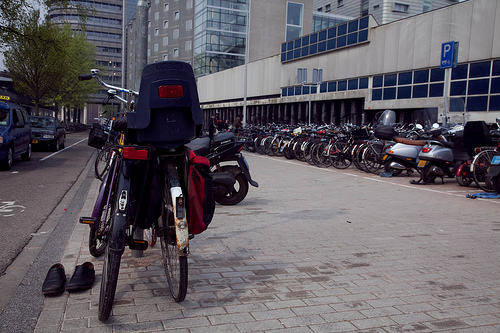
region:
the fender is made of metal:
[111, 155, 136, 245]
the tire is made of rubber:
[102, 245, 122, 321]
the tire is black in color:
[100, 246, 119, 321]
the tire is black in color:
[172, 248, 190, 300]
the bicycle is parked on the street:
[77, 78, 134, 320]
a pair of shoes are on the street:
[46, 259, 99, 297]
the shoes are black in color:
[44, 260, 94, 292]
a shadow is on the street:
[120, 244, 291, 331]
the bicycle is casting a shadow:
[109, 80, 306, 325]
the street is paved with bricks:
[56, 116, 479, 331]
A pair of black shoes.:
[40, 258, 99, 296]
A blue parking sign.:
[438, 37, 460, 72]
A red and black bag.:
[177, 142, 217, 234]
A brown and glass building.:
[193, 0, 315, 80]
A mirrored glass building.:
[122, 0, 193, 93]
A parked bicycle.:
[470, 121, 499, 191]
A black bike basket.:
[86, 120, 108, 150]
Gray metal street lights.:
[296, 67, 324, 127]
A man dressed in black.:
[206, 110, 220, 142]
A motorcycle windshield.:
[372, 110, 399, 131]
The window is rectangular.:
[369, 70, 385, 88]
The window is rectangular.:
[382, 68, 399, 87]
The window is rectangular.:
[395, 66, 414, 86]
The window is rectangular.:
[411, 61, 431, 84]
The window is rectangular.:
[428, 63, 448, 84]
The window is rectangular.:
[447, 59, 469, 81]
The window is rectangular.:
[466, 58, 493, 80]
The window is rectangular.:
[463, 74, 491, 96]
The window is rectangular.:
[463, 94, 492, 112]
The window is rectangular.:
[394, 83, 414, 100]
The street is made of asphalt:
[28, 163, 65, 200]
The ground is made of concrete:
[294, 206, 446, 305]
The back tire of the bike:
[89, 218, 138, 323]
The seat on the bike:
[121, 53, 210, 152]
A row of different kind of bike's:
[243, 118, 495, 190]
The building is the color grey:
[363, 23, 428, 62]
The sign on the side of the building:
[437, 36, 462, 71]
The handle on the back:
[73, 58, 138, 111]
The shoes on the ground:
[38, 258, 97, 298]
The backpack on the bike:
[181, 142, 222, 237]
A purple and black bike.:
[76, 58, 148, 325]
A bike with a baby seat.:
[102, 60, 217, 302]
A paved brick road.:
[35, 148, 499, 331]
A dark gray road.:
[0, 119, 93, 331]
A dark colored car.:
[27, 115, 68, 152]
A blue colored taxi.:
[0, 90, 33, 170]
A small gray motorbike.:
[415, 120, 468, 185]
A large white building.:
[193, 1, 498, 126]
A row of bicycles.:
[206, 118, 396, 174]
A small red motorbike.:
[455, 148, 486, 188]